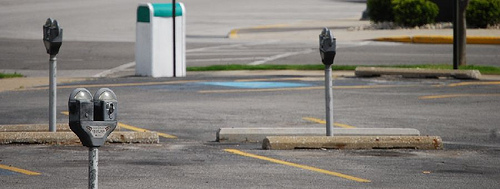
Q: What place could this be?
A: It is a parking lot.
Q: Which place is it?
A: It is a parking lot.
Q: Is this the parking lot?
A: Yes, it is the parking lot.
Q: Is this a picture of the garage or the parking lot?
A: It is showing the parking lot.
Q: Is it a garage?
A: No, it is a parking lot.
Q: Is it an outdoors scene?
A: Yes, it is outdoors.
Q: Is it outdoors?
A: Yes, it is outdoors.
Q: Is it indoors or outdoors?
A: It is outdoors.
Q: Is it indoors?
A: No, it is outdoors.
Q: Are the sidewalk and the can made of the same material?
A: No, the sidewalk is made of concrete and the can is made of metal.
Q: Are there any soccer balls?
A: No, there are no soccer balls.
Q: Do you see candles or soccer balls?
A: No, there are no soccer balls or candles.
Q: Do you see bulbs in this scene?
A: No, there are no bulbs.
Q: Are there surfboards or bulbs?
A: No, there are no bulbs or surfboards.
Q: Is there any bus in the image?
A: No, there are no buses.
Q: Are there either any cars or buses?
A: No, there are no buses or cars.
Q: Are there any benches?
A: No, there are no benches.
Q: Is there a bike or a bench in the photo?
A: No, there are no benches or bikes.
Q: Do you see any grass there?
A: Yes, there is grass.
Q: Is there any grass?
A: Yes, there is grass.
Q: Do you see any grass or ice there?
A: Yes, there is grass.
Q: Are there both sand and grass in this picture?
A: No, there is grass but no sand.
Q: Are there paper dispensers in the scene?
A: No, there are no paper dispensers.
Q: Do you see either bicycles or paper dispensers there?
A: No, there are no paper dispensers or bicycles.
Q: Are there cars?
A: No, there are no cars.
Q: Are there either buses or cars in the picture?
A: No, there are no cars or buses.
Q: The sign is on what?
A: The sign is on the parking meter.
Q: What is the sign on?
A: The sign is on the parking meter.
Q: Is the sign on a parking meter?
A: Yes, the sign is on a parking meter.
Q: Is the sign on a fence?
A: No, the sign is on a parking meter.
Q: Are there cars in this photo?
A: No, there are no cars.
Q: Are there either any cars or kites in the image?
A: No, there are no cars or kites.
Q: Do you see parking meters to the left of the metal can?
A: Yes, there is a parking meter to the left of the can.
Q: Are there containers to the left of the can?
A: No, there is a parking meter to the left of the can.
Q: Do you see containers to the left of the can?
A: No, there is a parking meter to the left of the can.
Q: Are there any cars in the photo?
A: No, there are no cars.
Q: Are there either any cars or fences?
A: No, there are no cars or fences.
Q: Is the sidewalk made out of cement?
A: Yes, the sidewalk is made of cement.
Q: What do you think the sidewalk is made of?
A: The sidewalk is made of concrete.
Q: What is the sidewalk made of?
A: The sidewalk is made of concrete.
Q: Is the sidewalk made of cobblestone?
A: No, the sidewalk is made of concrete.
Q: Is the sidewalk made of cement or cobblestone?
A: The sidewalk is made of cement.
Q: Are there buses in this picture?
A: No, there are no buses.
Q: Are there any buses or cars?
A: No, there are no buses or cars.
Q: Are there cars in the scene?
A: No, there are no cars.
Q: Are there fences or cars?
A: No, there are no cars or fences.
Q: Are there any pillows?
A: No, there are no pillows.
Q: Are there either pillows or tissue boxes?
A: No, there are no pillows or tissue boxes.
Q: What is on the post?
A: The parking meter is on the post.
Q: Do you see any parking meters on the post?
A: Yes, there is a parking meter on the post.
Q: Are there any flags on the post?
A: No, there is a parking meter on the post.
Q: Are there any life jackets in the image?
A: No, there are no life jackets.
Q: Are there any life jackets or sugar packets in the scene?
A: No, there are no life jackets or sugar packets.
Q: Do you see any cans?
A: Yes, there is a can.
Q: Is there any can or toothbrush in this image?
A: Yes, there is a can.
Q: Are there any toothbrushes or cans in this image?
A: Yes, there is a can.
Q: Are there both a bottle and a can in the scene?
A: No, there is a can but no bottles.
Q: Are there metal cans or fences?
A: Yes, there is a metal can.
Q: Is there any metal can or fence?
A: Yes, there is a metal can.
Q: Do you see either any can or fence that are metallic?
A: Yes, the can is metallic.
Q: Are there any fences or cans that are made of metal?
A: Yes, the can is made of metal.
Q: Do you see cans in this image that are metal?
A: Yes, there is a metal can.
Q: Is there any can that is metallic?
A: Yes, there is a can that is metallic.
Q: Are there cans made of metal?
A: Yes, there is a can that is made of metal.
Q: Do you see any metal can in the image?
A: Yes, there is a can that is made of metal.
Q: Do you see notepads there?
A: No, there are no notepads.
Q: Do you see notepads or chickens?
A: No, there are no notepads or chickens.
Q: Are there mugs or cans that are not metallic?
A: No, there is a can but it is metallic.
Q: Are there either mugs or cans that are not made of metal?
A: No, there is a can but it is made of metal.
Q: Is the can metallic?
A: Yes, the can is metallic.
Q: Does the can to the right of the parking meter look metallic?
A: Yes, the can is metallic.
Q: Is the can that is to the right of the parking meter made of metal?
A: Yes, the can is made of metal.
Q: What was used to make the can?
A: The can is made of metal.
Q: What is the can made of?
A: The can is made of metal.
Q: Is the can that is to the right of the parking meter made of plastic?
A: No, the can is made of metal.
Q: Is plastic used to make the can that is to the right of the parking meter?
A: No, the can is made of metal.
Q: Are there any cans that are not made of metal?
A: No, there is a can but it is made of metal.